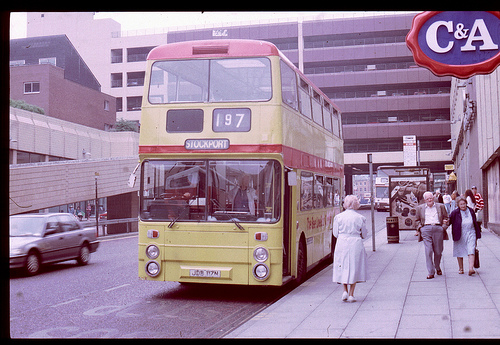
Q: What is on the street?
A: A red and yellow bus is on the street.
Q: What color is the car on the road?
A: There is a silver car on the road.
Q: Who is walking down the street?
A: A man and woman are walking down the sidewalk.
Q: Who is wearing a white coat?
A: A woman.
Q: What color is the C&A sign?
A: Red, blue and white.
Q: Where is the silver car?
A: Beside the bus.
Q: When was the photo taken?
A: During daylight hours.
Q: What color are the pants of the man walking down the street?
A: Grey.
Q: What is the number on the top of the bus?
A: 197.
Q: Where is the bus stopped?
A: On the street.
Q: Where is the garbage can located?
A: On the sidewalk.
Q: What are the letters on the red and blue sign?
A: C & A.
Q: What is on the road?
A: Bus.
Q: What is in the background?
A: Buildings.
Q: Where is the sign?
A: Over head.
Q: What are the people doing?
A: Walking.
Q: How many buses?
A: 1.